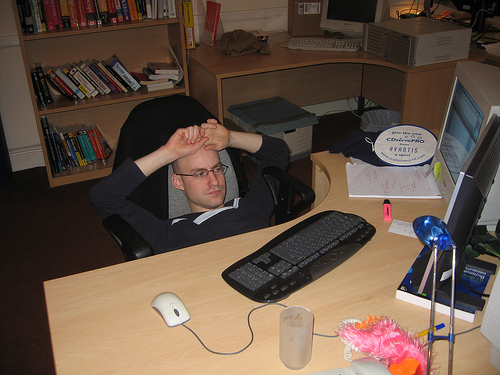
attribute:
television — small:
[429, 60, 498, 201]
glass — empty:
[278, 306, 313, 370]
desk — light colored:
[43, 151, 499, 374]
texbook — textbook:
[398, 245, 493, 323]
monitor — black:
[419, 113, 499, 295]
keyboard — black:
[220, 211, 377, 305]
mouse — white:
[153, 293, 189, 327]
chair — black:
[106, 92, 315, 257]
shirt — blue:
[88, 132, 291, 254]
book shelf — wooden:
[12, 2, 191, 190]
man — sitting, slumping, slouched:
[92, 117, 289, 254]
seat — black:
[103, 92, 316, 257]